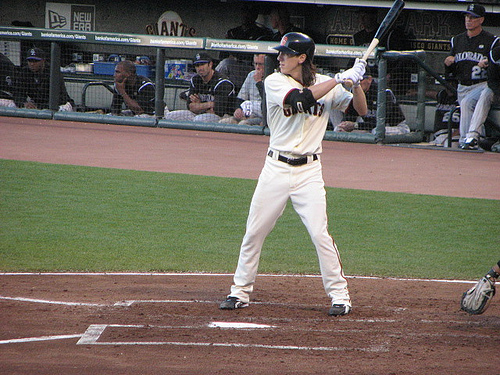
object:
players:
[443, 3, 500, 152]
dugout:
[0, 0, 456, 145]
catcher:
[458, 239, 500, 316]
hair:
[301, 61, 317, 88]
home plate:
[207, 316, 274, 331]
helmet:
[270, 31, 318, 62]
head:
[276, 36, 312, 75]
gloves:
[332, 66, 363, 87]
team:
[99, 45, 304, 129]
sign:
[41, 0, 96, 31]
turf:
[0, 154, 499, 284]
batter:
[212, 31, 370, 314]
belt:
[266, 151, 320, 168]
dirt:
[0, 272, 499, 375]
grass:
[0, 155, 499, 278]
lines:
[133, 283, 411, 314]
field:
[0, 111, 499, 375]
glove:
[457, 269, 500, 315]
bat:
[340, 0, 407, 90]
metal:
[0, 24, 375, 62]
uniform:
[228, 72, 353, 303]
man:
[213, 31, 368, 318]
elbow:
[285, 101, 317, 114]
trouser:
[226, 152, 353, 297]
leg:
[221, 180, 286, 303]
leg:
[291, 181, 348, 296]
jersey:
[258, 72, 352, 159]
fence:
[0, 26, 432, 145]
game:
[203, 31, 373, 317]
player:
[225, 31, 368, 308]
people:
[108, 59, 166, 118]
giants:
[143, 10, 197, 42]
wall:
[0, 4, 308, 62]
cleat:
[323, 303, 351, 319]